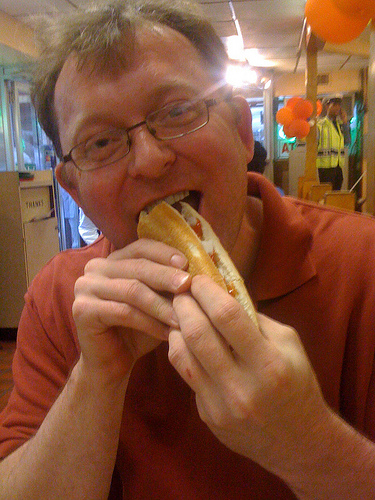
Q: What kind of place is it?
A: It is a restaurant.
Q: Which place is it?
A: It is a restaurant.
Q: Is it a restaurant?
A: Yes, it is a restaurant.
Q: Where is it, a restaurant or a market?
A: It is a restaurant.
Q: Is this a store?
A: No, it is a restaurant.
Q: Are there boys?
A: No, there are no boys.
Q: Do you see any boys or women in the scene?
A: No, there are no boys or women.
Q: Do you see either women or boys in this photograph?
A: No, there are no boys or women.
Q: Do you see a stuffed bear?
A: No, there are no stuffed bears.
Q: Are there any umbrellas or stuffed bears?
A: No, there are no stuffed bears or umbrellas.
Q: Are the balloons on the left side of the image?
A: No, the balloons are on the right of the image.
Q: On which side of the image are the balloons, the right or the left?
A: The balloons are on the right of the image.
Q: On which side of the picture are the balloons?
A: The balloons are on the right of the image.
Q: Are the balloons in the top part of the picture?
A: Yes, the balloons are in the top of the image.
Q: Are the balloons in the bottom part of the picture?
A: No, the balloons are in the top of the image.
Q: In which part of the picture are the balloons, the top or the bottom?
A: The balloons are in the top of the image.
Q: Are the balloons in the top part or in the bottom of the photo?
A: The balloons are in the top of the image.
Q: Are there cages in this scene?
A: No, there are no cages.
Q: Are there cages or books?
A: No, there are no cages or books.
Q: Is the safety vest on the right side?
A: Yes, the safety vest is on the right of the image.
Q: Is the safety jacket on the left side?
A: No, the safety jacket is on the right of the image.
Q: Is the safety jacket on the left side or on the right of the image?
A: The safety jacket is on the right of the image.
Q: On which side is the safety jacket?
A: The safety jacket is on the right of the image.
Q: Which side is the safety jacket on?
A: The safety jacket is on the right of the image.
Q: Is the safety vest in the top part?
A: Yes, the safety vest is in the top of the image.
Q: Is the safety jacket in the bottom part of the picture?
A: No, the safety jacket is in the top of the image.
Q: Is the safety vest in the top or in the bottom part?
A: The safety vest is in the top of the image.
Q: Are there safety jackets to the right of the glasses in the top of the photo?
A: Yes, there is a safety jacket to the right of the glasses.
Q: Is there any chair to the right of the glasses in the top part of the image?
A: No, there is a safety jacket to the right of the glasses.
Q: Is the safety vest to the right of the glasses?
A: Yes, the safety vest is to the right of the glasses.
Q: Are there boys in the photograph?
A: No, there are no boys.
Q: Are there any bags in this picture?
A: No, there are no bags.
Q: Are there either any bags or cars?
A: No, there are no bags or cars.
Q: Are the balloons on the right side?
A: Yes, the balloons are on the right of the image.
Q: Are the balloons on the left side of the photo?
A: No, the balloons are on the right of the image.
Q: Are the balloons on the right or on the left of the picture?
A: The balloons are on the right of the image.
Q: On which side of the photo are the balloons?
A: The balloons are on the right of the image.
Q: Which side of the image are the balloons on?
A: The balloons are on the right of the image.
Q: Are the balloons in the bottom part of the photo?
A: No, the balloons are in the top of the image.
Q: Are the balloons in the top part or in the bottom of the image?
A: The balloons are in the top of the image.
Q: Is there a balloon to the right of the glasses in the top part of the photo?
A: Yes, there are balloons to the right of the glasses.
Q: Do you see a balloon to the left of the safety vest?
A: Yes, there are balloons to the left of the safety vest.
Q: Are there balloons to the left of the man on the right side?
A: Yes, there are balloons to the left of the man.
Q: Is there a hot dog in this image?
A: Yes, there is a hot dog.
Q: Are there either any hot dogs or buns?
A: Yes, there is a hot dog.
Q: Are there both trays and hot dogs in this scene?
A: Yes, there are both a hot dog and a tray.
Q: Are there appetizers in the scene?
A: No, there are no appetizers.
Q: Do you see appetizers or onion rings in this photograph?
A: No, there are no appetizers or onion rings.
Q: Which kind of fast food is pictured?
A: The fast food is a hot dog.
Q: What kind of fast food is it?
A: The food is a hot dog.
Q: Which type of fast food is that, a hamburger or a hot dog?
A: This is a hot dog.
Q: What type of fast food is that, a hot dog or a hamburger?
A: This is a hot dog.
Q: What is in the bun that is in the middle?
A: The hot dog is in the bun.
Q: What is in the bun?
A: The hot dog is in the bun.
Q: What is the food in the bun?
A: The food is a hot dog.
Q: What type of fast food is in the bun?
A: The food is a hot dog.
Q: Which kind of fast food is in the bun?
A: The food is a hot dog.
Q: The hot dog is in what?
A: The hot dog is in the bun.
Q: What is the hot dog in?
A: The hot dog is in the bun.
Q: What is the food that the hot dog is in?
A: The food is a bun.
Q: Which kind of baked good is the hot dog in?
A: The hot dog is in the bun.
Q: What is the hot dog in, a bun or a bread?
A: The hot dog is in a bun.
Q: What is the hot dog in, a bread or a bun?
A: The hot dog is in a bun.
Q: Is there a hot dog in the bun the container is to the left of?
A: Yes, there is a hot dog in the bun.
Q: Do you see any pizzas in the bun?
A: No, there is a hot dog in the bun.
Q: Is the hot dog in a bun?
A: Yes, the hot dog is in a bun.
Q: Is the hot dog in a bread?
A: No, the hot dog is in a bun.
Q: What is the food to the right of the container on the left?
A: The food is a hot dog.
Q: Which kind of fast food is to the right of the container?
A: The food is a hot dog.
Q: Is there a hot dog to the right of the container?
A: Yes, there is a hot dog to the right of the container.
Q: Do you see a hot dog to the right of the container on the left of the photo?
A: Yes, there is a hot dog to the right of the container.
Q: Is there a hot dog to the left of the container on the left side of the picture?
A: No, the hot dog is to the right of the container.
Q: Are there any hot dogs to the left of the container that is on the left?
A: No, the hot dog is to the right of the container.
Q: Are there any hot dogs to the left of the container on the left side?
A: No, the hot dog is to the right of the container.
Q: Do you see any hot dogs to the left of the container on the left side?
A: No, the hot dog is to the right of the container.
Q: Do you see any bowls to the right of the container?
A: No, there is a hot dog to the right of the container.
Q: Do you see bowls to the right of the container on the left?
A: No, there is a hot dog to the right of the container.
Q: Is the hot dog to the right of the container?
A: Yes, the hot dog is to the right of the container.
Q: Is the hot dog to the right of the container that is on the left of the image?
A: Yes, the hot dog is to the right of the container.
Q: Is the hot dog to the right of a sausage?
A: No, the hot dog is to the right of the container.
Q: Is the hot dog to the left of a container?
A: No, the hot dog is to the right of a container.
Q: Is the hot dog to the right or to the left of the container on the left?
A: The hot dog is to the right of the container.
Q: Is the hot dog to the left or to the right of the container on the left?
A: The hot dog is to the right of the container.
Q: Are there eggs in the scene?
A: No, there are no eggs.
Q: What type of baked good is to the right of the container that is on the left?
A: The food is a bun.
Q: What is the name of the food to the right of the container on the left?
A: The food is a bun.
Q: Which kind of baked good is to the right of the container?
A: The food is a bun.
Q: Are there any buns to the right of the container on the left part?
A: Yes, there is a bun to the right of the container.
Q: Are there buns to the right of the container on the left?
A: Yes, there is a bun to the right of the container.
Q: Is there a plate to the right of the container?
A: No, there is a bun to the right of the container.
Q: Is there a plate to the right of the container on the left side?
A: No, there is a bun to the right of the container.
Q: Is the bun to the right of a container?
A: Yes, the bun is to the right of a container.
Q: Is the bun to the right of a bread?
A: No, the bun is to the right of a container.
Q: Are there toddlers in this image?
A: No, there are no toddlers.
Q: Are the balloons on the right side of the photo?
A: Yes, the balloons are on the right of the image.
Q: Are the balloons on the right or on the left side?
A: The balloons are on the right of the image.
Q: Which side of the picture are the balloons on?
A: The balloons are on the right of the image.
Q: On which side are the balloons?
A: The balloons are on the right of the image.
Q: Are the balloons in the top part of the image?
A: Yes, the balloons are in the top of the image.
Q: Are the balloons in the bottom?
A: No, the balloons are in the top of the image.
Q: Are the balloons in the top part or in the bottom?
A: The balloons are in the top of the image.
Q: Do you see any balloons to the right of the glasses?
A: Yes, there are balloons to the right of the glasses.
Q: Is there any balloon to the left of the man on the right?
A: Yes, there are balloons to the left of the man.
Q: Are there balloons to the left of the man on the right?
A: Yes, there are balloons to the left of the man.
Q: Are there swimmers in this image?
A: No, there are no swimmers.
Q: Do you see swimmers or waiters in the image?
A: No, there are no swimmers or waiters.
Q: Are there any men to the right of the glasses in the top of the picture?
A: Yes, there is a man to the right of the glasses.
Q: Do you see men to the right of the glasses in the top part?
A: Yes, there is a man to the right of the glasses.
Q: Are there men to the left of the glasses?
A: No, the man is to the right of the glasses.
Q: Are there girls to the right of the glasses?
A: No, there is a man to the right of the glasses.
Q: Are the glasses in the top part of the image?
A: Yes, the glasses are in the top of the image.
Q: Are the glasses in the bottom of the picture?
A: No, the glasses are in the top of the image.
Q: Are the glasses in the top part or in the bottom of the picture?
A: The glasses are in the top of the image.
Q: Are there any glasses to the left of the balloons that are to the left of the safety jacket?
A: Yes, there are glasses to the left of the balloons.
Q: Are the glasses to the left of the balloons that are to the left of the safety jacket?
A: Yes, the glasses are to the left of the balloons.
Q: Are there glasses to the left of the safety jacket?
A: Yes, there are glasses to the left of the safety jacket.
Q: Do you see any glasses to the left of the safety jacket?
A: Yes, there are glasses to the left of the safety jacket.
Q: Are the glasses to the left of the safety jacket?
A: Yes, the glasses are to the left of the safety jacket.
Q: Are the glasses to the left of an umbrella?
A: No, the glasses are to the left of the safety jacket.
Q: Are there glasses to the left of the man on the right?
A: Yes, there are glasses to the left of the man.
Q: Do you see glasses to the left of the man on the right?
A: Yes, there are glasses to the left of the man.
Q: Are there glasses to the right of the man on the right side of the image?
A: No, the glasses are to the left of the man.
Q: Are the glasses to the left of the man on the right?
A: Yes, the glasses are to the left of the man.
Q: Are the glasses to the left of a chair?
A: No, the glasses are to the left of the man.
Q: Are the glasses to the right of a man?
A: No, the glasses are to the left of a man.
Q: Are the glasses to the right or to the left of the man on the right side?
A: The glasses are to the left of the man.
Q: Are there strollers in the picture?
A: No, there are no strollers.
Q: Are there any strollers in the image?
A: No, there are no strollers.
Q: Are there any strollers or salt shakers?
A: No, there are no strollers or salt shakers.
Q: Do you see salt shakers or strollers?
A: No, there are no strollers or salt shakers.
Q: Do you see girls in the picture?
A: No, there are no girls.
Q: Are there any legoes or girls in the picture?
A: No, there are no girls or legoes.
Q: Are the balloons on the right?
A: Yes, the balloons are on the right of the image.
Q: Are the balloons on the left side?
A: No, the balloons are on the right of the image.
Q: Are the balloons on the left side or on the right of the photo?
A: The balloons are on the right of the image.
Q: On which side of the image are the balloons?
A: The balloons are on the right of the image.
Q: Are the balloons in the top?
A: Yes, the balloons are in the top of the image.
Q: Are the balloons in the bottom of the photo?
A: No, the balloons are in the top of the image.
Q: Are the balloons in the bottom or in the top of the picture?
A: The balloons are in the top of the image.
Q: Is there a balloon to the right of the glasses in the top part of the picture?
A: Yes, there are balloons to the right of the glasses.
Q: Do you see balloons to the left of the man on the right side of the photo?
A: Yes, there are balloons to the left of the man.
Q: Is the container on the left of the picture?
A: Yes, the container is on the left of the image.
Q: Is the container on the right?
A: No, the container is on the left of the image.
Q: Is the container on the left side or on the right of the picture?
A: The container is on the left of the image.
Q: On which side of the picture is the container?
A: The container is on the left of the image.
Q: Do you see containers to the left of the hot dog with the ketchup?
A: Yes, there is a container to the left of the hot dog.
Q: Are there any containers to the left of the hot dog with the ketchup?
A: Yes, there is a container to the left of the hot dog.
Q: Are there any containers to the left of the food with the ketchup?
A: Yes, there is a container to the left of the hot dog.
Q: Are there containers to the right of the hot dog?
A: No, the container is to the left of the hot dog.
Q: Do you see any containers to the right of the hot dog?
A: No, the container is to the left of the hot dog.